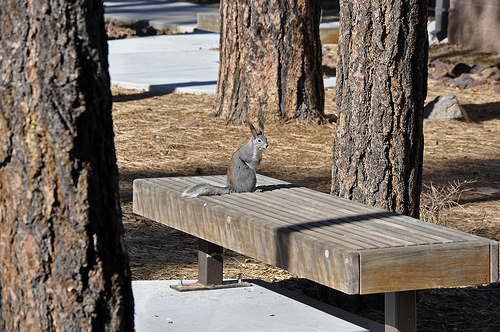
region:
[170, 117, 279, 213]
grey squirrel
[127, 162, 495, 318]
brown bench on a grey cement slab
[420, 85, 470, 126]
grey rock on the ground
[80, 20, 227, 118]
snow on the ground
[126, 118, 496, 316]
squirrel sitting on a bench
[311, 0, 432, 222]
tree trunk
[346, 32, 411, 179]
bark of a tree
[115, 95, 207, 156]
brown patch of ground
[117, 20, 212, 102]
snowy patch of ground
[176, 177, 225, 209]
tail of a grey squirrel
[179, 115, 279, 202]
gray rabbit on a bench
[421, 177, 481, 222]
shrub to the right of the bench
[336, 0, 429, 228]
tree trunk directly behind the bench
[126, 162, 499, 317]
wooden bench with metal legs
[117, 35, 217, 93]
light-colored cement in the background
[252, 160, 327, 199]
shadow cast by rabbit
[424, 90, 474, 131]
pointed rock to the right of the tree that is next to the bench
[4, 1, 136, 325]
tree in foreground on the left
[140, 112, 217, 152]
straw on the ground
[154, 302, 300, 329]
cement area in foreground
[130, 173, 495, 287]
brown wooden bench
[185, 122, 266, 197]
gray squirrel sitting on a bench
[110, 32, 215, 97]
light gray cement sidewalk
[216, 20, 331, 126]
large brown tree trunk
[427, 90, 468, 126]
small gray rock landscaping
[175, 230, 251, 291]
metal bench legs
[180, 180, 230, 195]
soft furry gray tail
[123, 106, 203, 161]
Dry brown landscaping material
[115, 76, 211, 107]
black tree shadow from the sun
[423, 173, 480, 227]
dry dead brown weed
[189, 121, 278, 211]
A squirrel perched on a bench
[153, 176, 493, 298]
A wooden bench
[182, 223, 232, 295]
Metal support under a wooden bench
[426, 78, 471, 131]
A rock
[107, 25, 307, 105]
A concrete drive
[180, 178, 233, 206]
A long gray squirrel tail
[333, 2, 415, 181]
Rough brown bark on the trunk of a tree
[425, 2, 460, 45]
A drain pipe attached to a building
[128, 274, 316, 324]
A concrete pad under a bench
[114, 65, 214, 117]
A shadow on the ground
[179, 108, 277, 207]
Squirrel on bench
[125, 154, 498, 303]
Bench is wood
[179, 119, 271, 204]
Squirrel is gray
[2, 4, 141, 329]
Trunk on left side of bench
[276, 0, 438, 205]
Trunks on right side of bench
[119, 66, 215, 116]
Shadow cast on ground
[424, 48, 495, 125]
Stones on ground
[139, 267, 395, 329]
Bench on concrete platform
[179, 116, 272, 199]
Squirrel face right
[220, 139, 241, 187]
Brown spot on back of squirrel